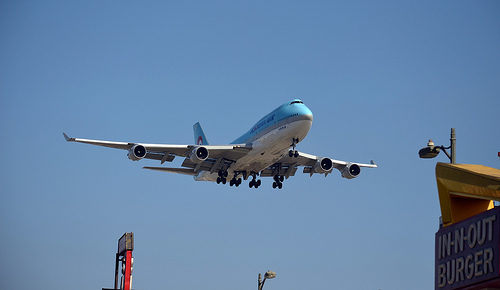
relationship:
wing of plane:
[68, 118, 190, 156] [50, 87, 383, 200]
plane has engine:
[50, 87, 383, 200] [128, 139, 156, 160]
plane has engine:
[50, 87, 383, 200] [180, 150, 218, 171]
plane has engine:
[50, 87, 383, 200] [311, 152, 333, 172]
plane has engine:
[50, 87, 383, 200] [340, 160, 362, 185]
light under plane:
[415, 119, 458, 160] [50, 87, 383, 200]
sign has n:
[424, 161, 496, 283] [453, 227, 465, 257]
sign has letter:
[424, 161, 496, 283] [463, 220, 477, 246]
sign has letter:
[424, 161, 496, 283] [478, 216, 489, 247]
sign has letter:
[424, 161, 496, 283] [485, 210, 499, 230]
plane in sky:
[50, 87, 383, 200] [119, 23, 173, 60]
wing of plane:
[302, 145, 380, 178] [50, 87, 383, 200]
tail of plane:
[183, 117, 214, 142] [50, 87, 383, 200]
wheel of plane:
[212, 169, 229, 186] [50, 87, 383, 200]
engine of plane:
[128, 139, 156, 160] [50, 87, 383, 200]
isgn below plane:
[104, 227, 137, 288] [50, 87, 383, 200]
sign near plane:
[424, 161, 496, 283] [50, 87, 383, 200]